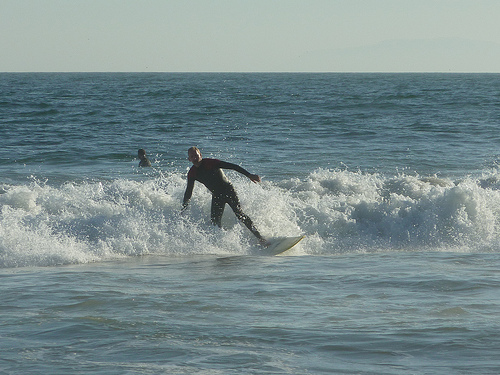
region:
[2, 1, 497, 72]
pale blue daytime sky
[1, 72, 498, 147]
surface of rough water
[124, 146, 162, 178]
head and shoulders of submerged person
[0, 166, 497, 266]
white water of crashing wave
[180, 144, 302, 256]
man standing on surfboard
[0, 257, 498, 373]
reflection on water surface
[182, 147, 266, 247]
man in black wetsuit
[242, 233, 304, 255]
foot on white surfboard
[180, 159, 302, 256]
surfer with extended arms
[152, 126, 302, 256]
water drops behind surfer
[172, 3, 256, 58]
this is the sky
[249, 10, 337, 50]
the sky is blue in color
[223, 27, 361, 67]
the sky has some clouds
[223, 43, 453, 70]
the clouds are white in color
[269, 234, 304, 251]
this is a surfboard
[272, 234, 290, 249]
the surfboard is white in color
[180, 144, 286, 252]
this is a man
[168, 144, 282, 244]
the man is on the surfboard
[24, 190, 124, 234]
this is raised water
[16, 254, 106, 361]
the water is blue in color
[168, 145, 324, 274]
A man with surfboard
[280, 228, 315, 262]
White color surfboard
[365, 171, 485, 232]
Big waves in the sea water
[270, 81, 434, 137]
A blue color sea water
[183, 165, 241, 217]
A person wearing black color dress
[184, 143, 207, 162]
Head of the person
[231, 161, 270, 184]
Hand of the person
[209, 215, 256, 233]
Legs of the person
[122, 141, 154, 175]
A person swimming the sea water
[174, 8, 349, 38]
A blue color sky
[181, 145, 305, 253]
a man riding a surfboard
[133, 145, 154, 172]
a person in the water behind a surfer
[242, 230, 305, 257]
surfboard the surfer is riding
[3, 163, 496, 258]
white water of a crashing wave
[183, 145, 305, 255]
surfer riding a wave into shore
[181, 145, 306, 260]
person surfing in on a wave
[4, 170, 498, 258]
water splashing around a surfer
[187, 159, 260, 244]
wetsuit the surfer is wearing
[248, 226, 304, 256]
front half of a surfboard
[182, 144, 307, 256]
a man riding on a surfboard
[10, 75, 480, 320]
surfer in front of low wave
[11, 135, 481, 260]
white water splashing around surfer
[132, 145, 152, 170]
head and shoulder above water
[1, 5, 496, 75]
clear gray sky above ocean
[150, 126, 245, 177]
drops of water in back of shoulders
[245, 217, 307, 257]
pointy end of slanted surfboard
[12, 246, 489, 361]
calm water in front of wave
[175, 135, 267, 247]
surfer covered in black wetsuit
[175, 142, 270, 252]
surfer leaning to one side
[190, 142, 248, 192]
light shining on side of face and body